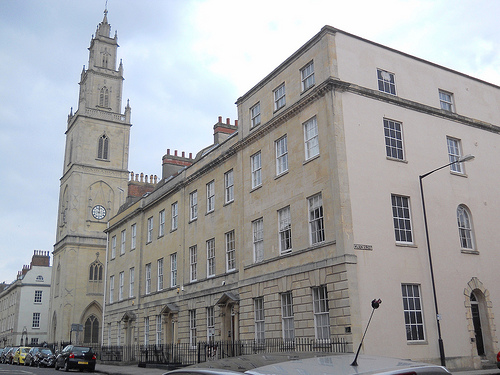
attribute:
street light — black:
[416, 152, 478, 374]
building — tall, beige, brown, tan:
[96, 16, 498, 374]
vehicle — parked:
[51, 343, 99, 374]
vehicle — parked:
[22, 345, 58, 367]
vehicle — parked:
[11, 345, 30, 365]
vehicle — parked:
[3, 344, 19, 365]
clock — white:
[90, 202, 110, 223]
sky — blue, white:
[0, 1, 498, 285]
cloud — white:
[183, 2, 435, 89]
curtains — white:
[306, 117, 319, 159]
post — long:
[419, 176, 447, 367]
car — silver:
[150, 295, 451, 375]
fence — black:
[67, 331, 352, 372]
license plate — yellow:
[76, 359, 90, 369]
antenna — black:
[346, 294, 385, 368]